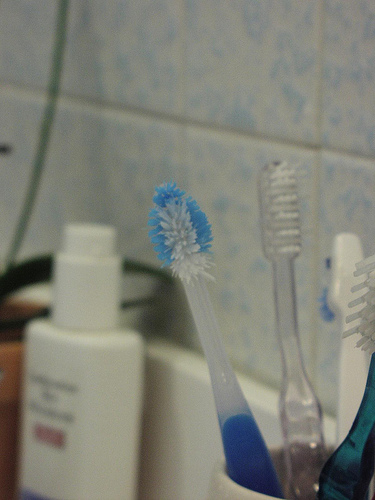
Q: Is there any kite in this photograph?
A: No, there are no kites.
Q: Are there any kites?
A: No, there are no kites.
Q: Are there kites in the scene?
A: No, there are no kites.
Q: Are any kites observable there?
A: No, there are no kites.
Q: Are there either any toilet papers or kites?
A: No, there are no kites or toilet papers.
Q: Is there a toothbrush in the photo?
A: Yes, there is a toothbrush.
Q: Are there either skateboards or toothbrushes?
A: Yes, there is a toothbrush.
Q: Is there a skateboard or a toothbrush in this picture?
A: Yes, there is a toothbrush.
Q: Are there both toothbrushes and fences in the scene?
A: No, there is a toothbrush but no fences.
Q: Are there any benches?
A: No, there are no benches.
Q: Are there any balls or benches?
A: No, there are no benches or balls.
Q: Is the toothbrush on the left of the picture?
A: No, the toothbrush is on the right of the image.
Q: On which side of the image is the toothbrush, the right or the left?
A: The toothbrush is on the right of the image.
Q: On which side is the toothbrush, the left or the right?
A: The toothbrush is on the right of the image.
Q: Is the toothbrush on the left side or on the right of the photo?
A: The toothbrush is on the right of the image.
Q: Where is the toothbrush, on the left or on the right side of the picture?
A: The toothbrush is on the right of the image.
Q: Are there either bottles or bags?
A: Yes, there is a bottle.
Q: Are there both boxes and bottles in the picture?
A: No, there is a bottle but no boxes.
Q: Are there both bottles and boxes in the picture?
A: No, there is a bottle but no boxes.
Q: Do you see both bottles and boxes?
A: No, there is a bottle but no boxes.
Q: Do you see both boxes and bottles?
A: No, there is a bottle but no boxes.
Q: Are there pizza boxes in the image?
A: No, there are no pizza boxes.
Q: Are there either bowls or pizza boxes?
A: No, there are no pizza boxes or bowls.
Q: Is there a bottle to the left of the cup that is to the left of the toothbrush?
A: Yes, there is a bottle to the left of the cup.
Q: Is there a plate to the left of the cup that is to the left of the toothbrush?
A: No, there is a bottle to the left of the cup.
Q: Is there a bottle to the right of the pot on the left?
A: Yes, there is a bottle to the right of the pot.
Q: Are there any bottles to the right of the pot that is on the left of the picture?
A: Yes, there is a bottle to the right of the pot.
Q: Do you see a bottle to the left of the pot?
A: No, the bottle is to the right of the pot.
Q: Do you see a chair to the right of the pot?
A: No, there is a bottle to the right of the pot.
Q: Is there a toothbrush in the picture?
A: Yes, there is a toothbrush.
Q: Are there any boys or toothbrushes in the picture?
A: Yes, there is a toothbrush.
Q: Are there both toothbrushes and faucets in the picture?
A: No, there is a toothbrush but no faucets.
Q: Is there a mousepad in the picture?
A: No, there are no mouse pads.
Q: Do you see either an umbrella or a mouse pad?
A: No, there are no mouse pads or umbrellas.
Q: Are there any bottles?
A: Yes, there is a bottle.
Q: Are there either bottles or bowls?
A: Yes, there is a bottle.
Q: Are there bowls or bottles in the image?
A: Yes, there is a bottle.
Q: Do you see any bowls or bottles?
A: Yes, there is a bottle.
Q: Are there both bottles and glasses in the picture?
A: No, there is a bottle but no glasses.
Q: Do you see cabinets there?
A: No, there are no cabinets.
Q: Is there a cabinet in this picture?
A: No, there are no cabinets.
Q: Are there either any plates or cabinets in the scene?
A: No, there are no cabinets or plates.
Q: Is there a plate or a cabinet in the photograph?
A: No, there are no cabinets or plates.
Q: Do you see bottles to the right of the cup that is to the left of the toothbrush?
A: No, the bottle is to the left of the cup.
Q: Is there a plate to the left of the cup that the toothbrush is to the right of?
A: No, there is a bottle to the left of the cup.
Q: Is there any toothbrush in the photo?
A: Yes, there is a toothbrush.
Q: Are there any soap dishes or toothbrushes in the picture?
A: Yes, there is a toothbrush.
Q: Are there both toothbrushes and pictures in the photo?
A: No, there is a toothbrush but no pictures.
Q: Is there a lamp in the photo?
A: No, there are no lamps.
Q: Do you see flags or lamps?
A: No, there are no lamps or flags.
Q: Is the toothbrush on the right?
A: Yes, the toothbrush is on the right of the image.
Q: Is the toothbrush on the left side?
A: No, the toothbrush is on the right of the image.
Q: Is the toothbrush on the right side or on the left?
A: The toothbrush is on the right of the image.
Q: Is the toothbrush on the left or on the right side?
A: The toothbrush is on the right of the image.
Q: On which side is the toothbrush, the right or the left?
A: The toothbrush is on the right of the image.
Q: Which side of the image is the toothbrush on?
A: The toothbrush is on the right of the image.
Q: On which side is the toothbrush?
A: The toothbrush is on the right of the image.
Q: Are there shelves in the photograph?
A: No, there are no shelves.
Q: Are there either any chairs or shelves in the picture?
A: No, there are no shelves or chairs.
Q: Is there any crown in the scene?
A: No, there are no crowns.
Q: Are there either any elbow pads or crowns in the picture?
A: No, there are no crowns or elbow pads.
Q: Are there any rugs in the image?
A: No, there are no rugs.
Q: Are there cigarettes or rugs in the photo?
A: No, there are no rugs or cigarettes.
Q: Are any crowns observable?
A: No, there are no crowns.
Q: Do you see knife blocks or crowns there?
A: No, there are no crowns or knife blocks.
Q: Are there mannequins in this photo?
A: No, there are no mannequins.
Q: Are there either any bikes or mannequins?
A: No, there are no mannequins or bikes.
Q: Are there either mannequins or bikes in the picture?
A: No, there are no mannequins or bikes.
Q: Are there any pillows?
A: No, there are no pillows.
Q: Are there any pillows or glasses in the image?
A: No, there are no pillows or glasses.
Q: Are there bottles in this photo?
A: Yes, there is a bottle.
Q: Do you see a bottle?
A: Yes, there is a bottle.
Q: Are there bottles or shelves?
A: Yes, there is a bottle.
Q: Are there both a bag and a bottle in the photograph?
A: No, there is a bottle but no bags.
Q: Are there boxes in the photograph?
A: No, there are no boxes.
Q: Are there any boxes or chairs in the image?
A: No, there are no boxes or chairs.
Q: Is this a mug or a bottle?
A: This is a bottle.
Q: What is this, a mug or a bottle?
A: This is a bottle.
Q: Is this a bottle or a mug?
A: This is a bottle.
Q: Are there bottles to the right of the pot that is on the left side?
A: Yes, there is a bottle to the right of the pot.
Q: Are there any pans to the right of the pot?
A: No, there is a bottle to the right of the pot.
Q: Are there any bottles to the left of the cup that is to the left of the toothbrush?
A: Yes, there is a bottle to the left of the cup.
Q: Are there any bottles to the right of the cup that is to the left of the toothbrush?
A: No, the bottle is to the left of the cup.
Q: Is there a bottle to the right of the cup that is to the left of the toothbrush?
A: No, the bottle is to the left of the cup.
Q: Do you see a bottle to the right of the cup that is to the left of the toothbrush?
A: No, the bottle is to the left of the cup.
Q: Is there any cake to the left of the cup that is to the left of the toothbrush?
A: No, there is a bottle to the left of the cup.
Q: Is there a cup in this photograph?
A: Yes, there is a cup.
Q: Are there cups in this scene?
A: Yes, there is a cup.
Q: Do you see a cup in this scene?
A: Yes, there is a cup.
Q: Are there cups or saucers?
A: Yes, there is a cup.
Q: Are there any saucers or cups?
A: Yes, there is a cup.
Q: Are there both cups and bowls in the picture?
A: No, there is a cup but no bowls.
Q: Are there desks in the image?
A: No, there are no desks.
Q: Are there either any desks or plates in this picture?
A: No, there are no desks or plates.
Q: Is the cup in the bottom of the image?
A: Yes, the cup is in the bottom of the image.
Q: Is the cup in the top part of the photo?
A: No, the cup is in the bottom of the image.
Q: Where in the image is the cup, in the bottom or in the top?
A: The cup is in the bottom of the image.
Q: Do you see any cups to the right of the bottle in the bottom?
A: Yes, there is a cup to the right of the bottle.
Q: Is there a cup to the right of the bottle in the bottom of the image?
A: Yes, there is a cup to the right of the bottle.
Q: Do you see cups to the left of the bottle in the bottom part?
A: No, the cup is to the right of the bottle.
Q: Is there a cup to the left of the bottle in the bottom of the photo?
A: No, the cup is to the right of the bottle.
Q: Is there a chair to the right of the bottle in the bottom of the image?
A: No, there is a cup to the right of the bottle.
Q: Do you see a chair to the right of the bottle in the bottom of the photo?
A: No, there is a cup to the right of the bottle.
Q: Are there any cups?
A: Yes, there is a cup.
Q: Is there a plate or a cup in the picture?
A: Yes, there is a cup.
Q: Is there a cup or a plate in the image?
A: Yes, there is a cup.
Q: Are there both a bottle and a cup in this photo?
A: Yes, there are both a cup and a bottle.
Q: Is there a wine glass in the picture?
A: No, there are no wine glasses.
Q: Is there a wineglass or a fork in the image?
A: No, there are no wine glasses or forks.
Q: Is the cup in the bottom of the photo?
A: Yes, the cup is in the bottom of the image.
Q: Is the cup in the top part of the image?
A: No, the cup is in the bottom of the image.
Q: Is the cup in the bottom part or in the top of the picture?
A: The cup is in the bottom of the image.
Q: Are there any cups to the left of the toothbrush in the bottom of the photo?
A: Yes, there is a cup to the left of the toothbrush.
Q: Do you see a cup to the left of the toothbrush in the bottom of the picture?
A: Yes, there is a cup to the left of the toothbrush.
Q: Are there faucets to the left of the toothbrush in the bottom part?
A: No, there is a cup to the left of the toothbrush.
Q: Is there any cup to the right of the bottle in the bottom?
A: Yes, there is a cup to the right of the bottle.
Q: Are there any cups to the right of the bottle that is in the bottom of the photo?
A: Yes, there is a cup to the right of the bottle.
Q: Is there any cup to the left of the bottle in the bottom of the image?
A: No, the cup is to the right of the bottle.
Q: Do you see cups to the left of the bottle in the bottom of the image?
A: No, the cup is to the right of the bottle.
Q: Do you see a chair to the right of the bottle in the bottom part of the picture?
A: No, there is a cup to the right of the bottle.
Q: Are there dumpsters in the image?
A: No, there are no dumpsters.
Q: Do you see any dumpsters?
A: No, there are no dumpsters.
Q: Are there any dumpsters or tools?
A: No, there are no dumpsters or tools.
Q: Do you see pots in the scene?
A: Yes, there is a pot.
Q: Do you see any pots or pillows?
A: Yes, there is a pot.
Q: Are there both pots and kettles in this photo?
A: No, there is a pot but no kettles.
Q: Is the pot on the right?
A: No, the pot is on the left of the image.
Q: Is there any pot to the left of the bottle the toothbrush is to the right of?
A: Yes, there is a pot to the left of the bottle.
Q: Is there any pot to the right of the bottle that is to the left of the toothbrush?
A: No, the pot is to the left of the bottle.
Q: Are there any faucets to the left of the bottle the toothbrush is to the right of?
A: No, there is a pot to the left of the bottle.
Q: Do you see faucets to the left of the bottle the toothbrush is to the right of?
A: No, there is a pot to the left of the bottle.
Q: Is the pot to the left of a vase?
A: No, the pot is to the left of the bottle.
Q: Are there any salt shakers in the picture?
A: No, there are no salt shakers.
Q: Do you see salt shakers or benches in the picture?
A: No, there are no salt shakers or benches.